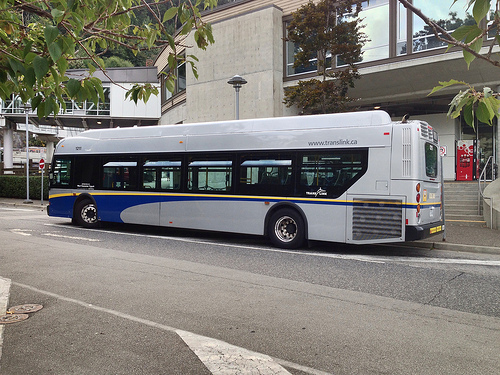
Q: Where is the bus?
A: On side of the street.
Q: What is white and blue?
A: Bus.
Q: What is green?
A: Leaves.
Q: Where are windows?
A: On a building.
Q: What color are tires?
A: Black.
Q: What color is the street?
A: Grey.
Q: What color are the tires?
A: Black.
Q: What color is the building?
A: Gray.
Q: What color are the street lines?
A: White.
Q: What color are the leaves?
A: Green.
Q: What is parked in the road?
A: A bus.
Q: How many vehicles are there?
A: One.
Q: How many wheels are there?
A: Two.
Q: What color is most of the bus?
A: Gray.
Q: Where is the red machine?
A: By the building.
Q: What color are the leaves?
A: Green.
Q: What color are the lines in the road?
A: White.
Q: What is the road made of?
A: Asphalt.